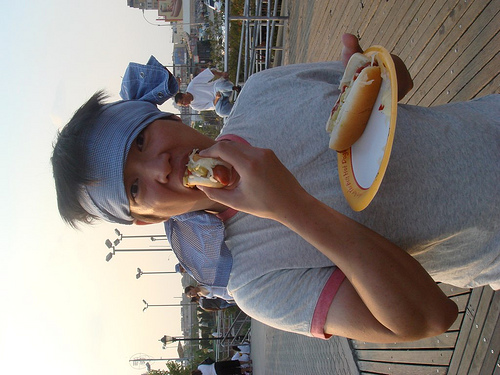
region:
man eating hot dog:
[20, 36, 414, 322]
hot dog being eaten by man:
[45, 68, 299, 262]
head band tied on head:
[52, 57, 169, 233]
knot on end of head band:
[89, 40, 184, 119]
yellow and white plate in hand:
[317, 31, 399, 221]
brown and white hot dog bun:
[317, 45, 382, 160]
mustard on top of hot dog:
[175, 160, 211, 177]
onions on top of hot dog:
[178, 160, 214, 187]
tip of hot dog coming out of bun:
[207, 160, 229, 189]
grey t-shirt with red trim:
[197, 14, 477, 349]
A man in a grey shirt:
[48, 29, 499, 346]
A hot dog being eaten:
[180, 150, 227, 195]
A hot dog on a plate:
[322, 48, 381, 156]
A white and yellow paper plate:
[334, 43, 399, 211]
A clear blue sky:
[0, 0, 183, 372]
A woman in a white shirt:
[180, 281, 230, 303]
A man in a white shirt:
[170, 60, 235, 116]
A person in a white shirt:
[192, 357, 245, 372]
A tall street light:
[98, 238, 172, 263]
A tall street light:
[109, 227, 165, 245]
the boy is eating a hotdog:
[51, 35, 496, 340]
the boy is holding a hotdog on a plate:
[325, 52, 385, 154]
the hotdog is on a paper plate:
[330, 42, 400, 210]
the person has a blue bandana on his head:
[49, 55, 180, 230]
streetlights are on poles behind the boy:
[101, 223, 197, 315]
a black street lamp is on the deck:
[156, 331, 248, 347]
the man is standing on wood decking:
[277, 1, 499, 371]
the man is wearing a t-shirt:
[221, 60, 495, 334]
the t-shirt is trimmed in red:
[215, 203, 358, 341]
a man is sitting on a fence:
[163, 40, 278, 131]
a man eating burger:
[69, 99, 456, 271]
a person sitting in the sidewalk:
[165, 71, 245, 112]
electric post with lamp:
[96, 235, 190, 309]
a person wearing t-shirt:
[205, 117, 487, 294]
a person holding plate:
[312, 35, 421, 210]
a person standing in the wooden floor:
[429, 30, 497, 84]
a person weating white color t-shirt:
[186, 73, 223, 114]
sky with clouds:
[16, 15, 63, 92]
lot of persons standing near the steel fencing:
[176, 279, 236, 374]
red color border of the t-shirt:
[311, 260, 338, 350]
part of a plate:
[368, 169, 376, 190]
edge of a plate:
[368, 163, 382, 185]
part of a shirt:
[424, 227, 430, 232]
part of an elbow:
[443, 306, 447, 317]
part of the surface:
[412, 343, 425, 353]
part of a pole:
[157, 288, 169, 315]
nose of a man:
[160, 160, 170, 174]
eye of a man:
[135, 179, 147, 190]